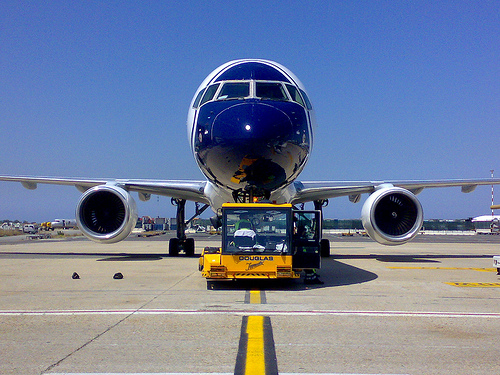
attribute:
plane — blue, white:
[49, 67, 393, 274]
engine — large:
[353, 181, 431, 248]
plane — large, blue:
[2, 55, 499, 271]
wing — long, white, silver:
[300, 176, 499, 193]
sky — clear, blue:
[62, 47, 133, 122]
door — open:
[283, 205, 324, 276]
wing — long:
[2, 171, 207, 243]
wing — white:
[299, 176, 499, 246]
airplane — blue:
[81, 42, 416, 301]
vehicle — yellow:
[198, 199, 305, 286]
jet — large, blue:
[0, 56, 499, 256]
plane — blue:
[46, 47, 466, 323]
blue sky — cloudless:
[334, 29, 482, 154]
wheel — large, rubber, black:
[165, 237, 200, 256]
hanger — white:
[471, 210, 498, 233]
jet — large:
[82, 45, 457, 353]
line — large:
[235, 313, 286, 373]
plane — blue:
[64, 62, 434, 264]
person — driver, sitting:
[235, 220, 257, 254]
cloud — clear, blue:
[316, 86, 488, 155]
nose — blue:
[206, 97, 303, 187]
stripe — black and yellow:
[202, 303, 325, 364]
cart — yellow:
[195, 201, 330, 288]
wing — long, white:
[0, 164, 215, 214]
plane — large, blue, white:
[1, 54, 498, 307]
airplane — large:
[12, 49, 493, 256]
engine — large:
[361, 186, 425, 246]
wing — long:
[0, 169, 483, 239]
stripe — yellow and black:
[230, 287, 279, 371]